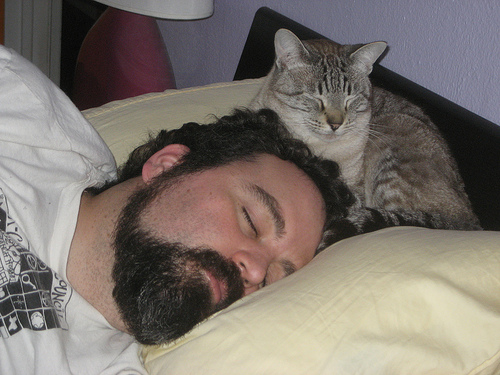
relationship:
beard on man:
[113, 183, 243, 344] [0, 45, 365, 375]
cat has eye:
[244, 25, 487, 257] [304, 88, 321, 104]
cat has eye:
[244, 25, 487, 257] [345, 95, 357, 106]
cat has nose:
[244, 25, 487, 257] [327, 115, 344, 129]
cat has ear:
[244, 25, 487, 257] [271, 25, 310, 68]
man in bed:
[0, 45, 365, 375] [3, 7, 499, 368]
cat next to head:
[244, 25, 487, 257] [97, 105, 349, 348]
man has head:
[0, 45, 365, 375] [97, 105, 349, 348]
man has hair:
[0, 45, 365, 375] [112, 109, 361, 253]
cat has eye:
[244, 25, 487, 257] [304, 93, 323, 105]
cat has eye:
[244, 25, 487, 257] [340, 97, 360, 107]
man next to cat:
[0, 45, 365, 375] [244, 25, 487, 257]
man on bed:
[0, 45, 365, 375] [3, 7, 499, 368]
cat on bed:
[244, 25, 487, 257] [3, 7, 499, 368]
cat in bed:
[244, 25, 487, 257] [3, 7, 499, 368]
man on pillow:
[0, 45, 365, 375] [86, 68, 498, 373]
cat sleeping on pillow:
[244, 25, 487, 257] [86, 68, 498, 373]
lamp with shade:
[74, 5, 180, 105] [96, 2, 227, 27]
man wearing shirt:
[0, 45, 365, 375] [0, 41, 164, 371]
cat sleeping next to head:
[244, 25, 487, 257] [110, 95, 360, 355]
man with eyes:
[0, 45, 365, 375] [239, 191, 289, 291]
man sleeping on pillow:
[0, 45, 365, 375] [86, 68, 498, 373]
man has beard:
[0, 45, 365, 375] [99, 165, 249, 360]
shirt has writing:
[0, 41, 164, 371] [1, 175, 79, 360]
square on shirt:
[38, 301, 68, 339] [0, 41, 164, 371]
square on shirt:
[21, 304, 48, 338] [0, 41, 164, 371]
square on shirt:
[15, 248, 35, 280] [0, 41, 164, 371]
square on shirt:
[19, 288, 49, 318] [4, 34, 144, 373]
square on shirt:
[1, 310, 28, 339] [0, 41, 164, 371]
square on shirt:
[2, 294, 15, 321] [0, 41, 164, 371]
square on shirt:
[10, 290, 32, 312] [0, 41, 164, 371]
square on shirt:
[0, 229, 70, 340] [0, 41, 164, 371]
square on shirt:
[21, 267, 36, 296] [0, 41, 164, 371]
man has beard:
[0, 45, 365, 375] [111, 177, 209, 347]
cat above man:
[244, 25, 487, 257] [105, 108, 345, 371]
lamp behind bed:
[62, 0, 219, 113] [36, 8, 290, 135]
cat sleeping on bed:
[244, 25, 487, 257] [319, 244, 477, 373]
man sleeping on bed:
[0, 45, 365, 375] [333, 226, 484, 373]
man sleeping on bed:
[2, 110, 328, 370] [333, 226, 484, 373]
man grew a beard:
[2, 110, 328, 370] [115, 236, 244, 342]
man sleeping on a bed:
[2, 110, 328, 370] [320, 230, 479, 370]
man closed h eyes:
[2, 110, 328, 370] [239, 202, 260, 239]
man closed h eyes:
[2, 110, 328, 370] [242, 199, 263, 244]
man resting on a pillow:
[2, 110, 328, 370] [348, 230, 482, 367]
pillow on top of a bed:
[79, 74, 500, 375] [75, 0, 285, 123]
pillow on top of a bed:
[348, 230, 482, 367] [465, 101, 484, 370]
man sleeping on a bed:
[0, 45, 365, 375] [469, 96, 485, 371]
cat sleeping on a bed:
[244, 25, 487, 257] [469, 96, 485, 371]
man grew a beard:
[0, 45, 365, 375] [119, 244, 236, 342]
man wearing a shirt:
[2, 110, 328, 370] [7, 44, 119, 373]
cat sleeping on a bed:
[269, 30, 389, 131] [469, 96, 485, 371]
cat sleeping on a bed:
[244, 25, 487, 257] [475, 104, 484, 359]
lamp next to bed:
[62, 0, 219, 113] [460, 4, 484, 371]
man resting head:
[0, 45, 365, 375] [73, 103, 354, 340]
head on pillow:
[73, 103, 354, 340] [299, 271, 439, 372]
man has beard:
[0, 45, 365, 375] [115, 168, 227, 356]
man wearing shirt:
[0, 45, 365, 375] [0, 37, 133, 372]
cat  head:
[244, 25, 487, 257] [269, 19, 388, 150]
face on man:
[116, 152, 331, 348] [0, 45, 365, 375]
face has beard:
[127, 126, 342, 337] [146, 246, 243, 352]